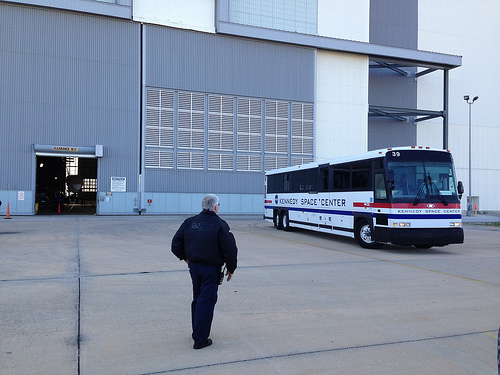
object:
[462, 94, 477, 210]
pole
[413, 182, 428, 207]
windshield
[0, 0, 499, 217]
building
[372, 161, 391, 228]
door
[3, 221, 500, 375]
ground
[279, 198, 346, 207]
words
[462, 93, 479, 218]
light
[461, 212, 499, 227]
sidewalk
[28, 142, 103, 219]
garage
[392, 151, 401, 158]
number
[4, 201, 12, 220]
cone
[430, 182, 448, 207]
windshield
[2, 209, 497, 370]
parking lot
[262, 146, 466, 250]
bus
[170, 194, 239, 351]
bus driver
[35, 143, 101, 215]
opening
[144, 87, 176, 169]
window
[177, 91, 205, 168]
window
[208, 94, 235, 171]
window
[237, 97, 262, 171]
window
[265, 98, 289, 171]
window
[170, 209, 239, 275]
jacket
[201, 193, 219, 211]
hair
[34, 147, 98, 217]
door